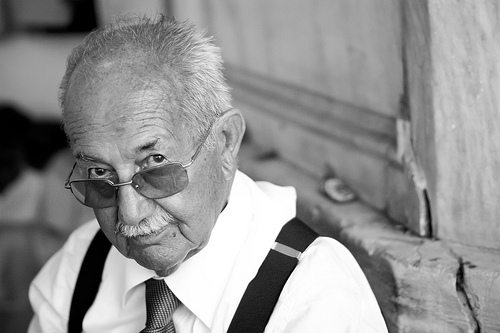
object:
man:
[24, 12, 391, 332]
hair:
[57, 17, 234, 152]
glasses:
[62, 125, 216, 209]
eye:
[86, 166, 111, 181]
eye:
[144, 153, 167, 167]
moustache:
[112, 211, 176, 237]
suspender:
[223, 217, 320, 332]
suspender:
[67, 228, 112, 333]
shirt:
[26, 169, 386, 333]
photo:
[0, 1, 500, 333]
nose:
[116, 168, 153, 226]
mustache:
[111, 206, 178, 237]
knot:
[138, 324, 173, 333]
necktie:
[139, 277, 181, 332]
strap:
[224, 216, 318, 332]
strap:
[64, 228, 111, 333]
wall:
[230, 0, 500, 330]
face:
[64, 114, 220, 272]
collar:
[114, 258, 246, 331]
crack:
[419, 189, 482, 333]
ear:
[217, 108, 246, 182]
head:
[58, 12, 247, 273]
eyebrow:
[73, 138, 161, 164]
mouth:
[122, 225, 173, 246]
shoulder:
[244, 232, 365, 276]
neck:
[146, 245, 213, 278]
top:
[54, 14, 218, 64]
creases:
[62, 107, 179, 149]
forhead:
[60, 47, 179, 118]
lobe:
[220, 153, 238, 180]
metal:
[268, 240, 304, 261]